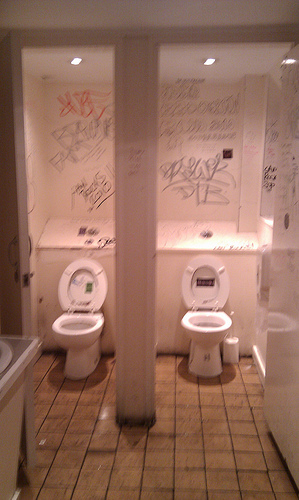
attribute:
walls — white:
[46, 129, 87, 209]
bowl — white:
[40, 277, 133, 353]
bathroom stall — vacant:
[154, 78, 264, 374]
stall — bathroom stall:
[165, 45, 290, 365]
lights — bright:
[62, 53, 297, 77]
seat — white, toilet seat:
[180, 310, 238, 345]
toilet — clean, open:
[178, 252, 234, 378]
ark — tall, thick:
[108, 39, 170, 420]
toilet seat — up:
[181, 255, 231, 310]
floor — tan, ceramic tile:
[161, 388, 259, 484]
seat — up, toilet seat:
[52, 256, 107, 375]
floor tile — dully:
[175, 390, 200, 407]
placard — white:
[115, 30, 154, 425]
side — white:
[268, 341, 290, 420]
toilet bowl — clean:
[177, 308, 233, 379]